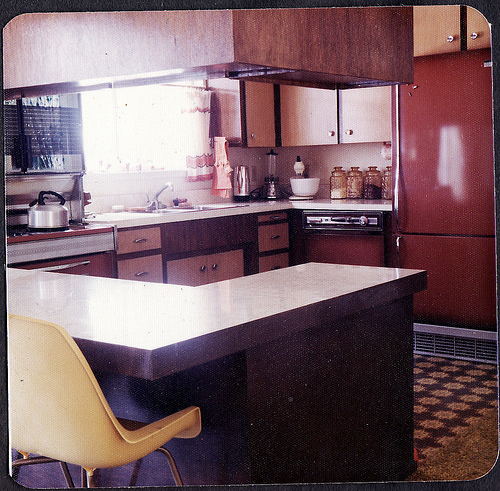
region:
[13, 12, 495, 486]
a scene inside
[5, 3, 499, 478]
an image in a kitchen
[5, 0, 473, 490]
a scene during the day time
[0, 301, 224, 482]
a white chair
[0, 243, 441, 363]
a white counter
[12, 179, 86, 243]
a silver teapot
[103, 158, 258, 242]
a silver sink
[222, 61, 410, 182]
a white cupboard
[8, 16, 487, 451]
this is a kitchen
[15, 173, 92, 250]
a silver tea kettle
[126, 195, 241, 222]
this is a sink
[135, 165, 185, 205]
this is a faucet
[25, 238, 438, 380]
a white shiny counter top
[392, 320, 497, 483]
linoleum on the floor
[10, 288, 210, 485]
this is a stool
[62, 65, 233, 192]
a window in the kitchen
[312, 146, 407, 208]
a set of canisters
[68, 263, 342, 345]
the counter is empty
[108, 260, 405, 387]
the counter is empty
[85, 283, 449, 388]
the counter is empty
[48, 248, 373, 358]
the counter is empty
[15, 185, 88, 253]
kettle on the stove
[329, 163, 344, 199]
a countertop food jar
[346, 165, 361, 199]
a countertop food jar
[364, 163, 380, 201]
a countertop food jar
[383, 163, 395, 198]
a countertop food jar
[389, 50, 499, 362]
a dark brown paneled refrigerator freezer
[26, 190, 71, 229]
a silver and black tea pot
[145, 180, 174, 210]
a chrome kitchen faucet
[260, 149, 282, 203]
a kitchen blender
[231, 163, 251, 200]
a chrome coffee pot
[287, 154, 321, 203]
a white electric mixing bowl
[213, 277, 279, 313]
a counter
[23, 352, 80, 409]
the back of a chair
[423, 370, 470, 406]
the tile in the kitchen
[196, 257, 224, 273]
knobs on the counter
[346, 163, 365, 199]
glass container on the counter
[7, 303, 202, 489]
chair is under counter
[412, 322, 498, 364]
vent is on the floor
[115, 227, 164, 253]
drawers is under sink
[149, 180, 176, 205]
faucet is over sink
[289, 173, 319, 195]
bowl is on the counter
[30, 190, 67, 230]
kettle is on top of stove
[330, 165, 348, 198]
jar is up against the wall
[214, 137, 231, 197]
dish towel is beside the window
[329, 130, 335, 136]
knob is on the cabinet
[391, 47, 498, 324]
fridge is red